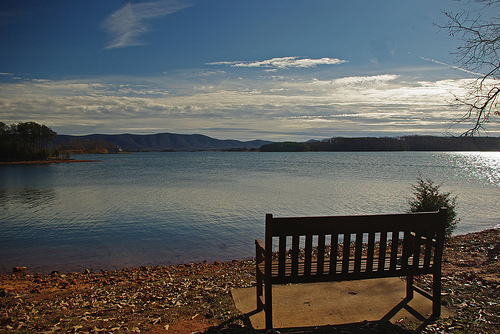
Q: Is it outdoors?
A: Yes, it is outdoors.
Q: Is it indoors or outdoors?
A: It is outdoors.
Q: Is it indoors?
A: No, it is outdoors.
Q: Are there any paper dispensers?
A: No, there are no paper dispensers.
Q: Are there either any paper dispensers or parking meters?
A: No, there are no paper dispensers or parking meters.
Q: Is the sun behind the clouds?
A: Yes, the sun is behind the clouds.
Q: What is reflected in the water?
A: The sun is reflected in the water.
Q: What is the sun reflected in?
A: The sun is reflected in the water.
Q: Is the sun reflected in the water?
A: Yes, the sun is reflected in the water.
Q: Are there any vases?
A: No, there are no vases.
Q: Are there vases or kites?
A: No, there are no vases or kites.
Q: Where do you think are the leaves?
A: The leaves are on the ground.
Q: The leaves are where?
A: The leaves are on the ground.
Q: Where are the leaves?
A: The leaves are on the ground.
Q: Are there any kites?
A: No, there are no kites.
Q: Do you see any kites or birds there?
A: No, there are no kites or birds.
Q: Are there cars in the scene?
A: No, there are no cars.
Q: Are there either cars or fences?
A: No, there are no cars or fences.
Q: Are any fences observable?
A: No, there are no fences.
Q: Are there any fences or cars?
A: No, there are no fences or cars.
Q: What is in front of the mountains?
A: The trees are in front of the mountains.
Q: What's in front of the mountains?
A: The trees are in front of the mountains.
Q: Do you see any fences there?
A: No, there are no fences.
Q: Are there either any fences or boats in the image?
A: No, there are no fences or boats.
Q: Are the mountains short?
A: Yes, the mountains are short.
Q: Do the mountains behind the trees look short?
A: Yes, the mountains are short.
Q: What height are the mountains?
A: The mountains are short.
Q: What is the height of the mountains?
A: The mountains are short.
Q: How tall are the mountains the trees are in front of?
A: The mountains are short.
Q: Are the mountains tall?
A: No, the mountains are short.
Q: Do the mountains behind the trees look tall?
A: No, the mountains are short.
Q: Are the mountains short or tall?
A: The mountains are short.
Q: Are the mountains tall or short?
A: The mountains are short.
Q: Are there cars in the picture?
A: No, there are no cars.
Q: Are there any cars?
A: No, there are no cars.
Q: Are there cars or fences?
A: No, there are no cars or fences.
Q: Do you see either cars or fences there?
A: No, there are no cars or fences.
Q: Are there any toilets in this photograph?
A: No, there are no toilets.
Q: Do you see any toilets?
A: No, there are no toilets.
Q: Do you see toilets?
A: No, there are no toilets.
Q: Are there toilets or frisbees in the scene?
A: No, there are no toilets or frisbees.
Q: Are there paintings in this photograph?
A: No, there are no paintings.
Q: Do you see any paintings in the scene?
A: No, there are no paintings.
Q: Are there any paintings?
A: No, there are no paintings.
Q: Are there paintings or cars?
A: No, there are no paintings or cars.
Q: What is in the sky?
A: The clouds are in the sky.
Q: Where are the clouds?
A: The clouds are in the sky.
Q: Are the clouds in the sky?
A: Yes, the clouds are in the sky.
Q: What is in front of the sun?
A: The clouds are in front of the sun.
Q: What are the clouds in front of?
A: The clouds are in front of the sun.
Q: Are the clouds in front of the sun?
A: Yes, the clouds are in front of the sun.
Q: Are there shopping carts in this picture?
A: No, there are no shopping carts.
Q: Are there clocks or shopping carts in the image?
A: No, there are no shopping carts or clocks.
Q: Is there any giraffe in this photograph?
A: No, there are no giraffes.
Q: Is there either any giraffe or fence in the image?
A: No, there are no giraffes or fences.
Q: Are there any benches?
A: Yes, there is a bench.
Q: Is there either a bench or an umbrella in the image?
A: Yes, there is a bench.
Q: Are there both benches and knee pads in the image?
A: No, there is a bench but no knee pads.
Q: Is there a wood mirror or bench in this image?
A: Yes, there is a wood bench.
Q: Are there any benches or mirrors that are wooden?
A: Yes, the bench is wooden.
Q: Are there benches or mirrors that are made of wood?
A: Yes, the bench is made of wood.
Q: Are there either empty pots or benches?
A: Yes, there is an empty bench.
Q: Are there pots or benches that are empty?
A: Yes, the bench is empty.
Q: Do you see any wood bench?
A: Yes, there is a wood bench.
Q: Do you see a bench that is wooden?
A: Yes, there is a bench that is wooden.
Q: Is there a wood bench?
A: Yes, there is a bench that is made of wood.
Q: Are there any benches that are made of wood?
A: Yes, there is a bench that is made of wood.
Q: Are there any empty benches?
A: Yes, there is an empty bench.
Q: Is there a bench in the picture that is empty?
A: Yes, there is a bench that is empty.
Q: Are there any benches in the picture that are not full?
A: Yes, there is a empty bench.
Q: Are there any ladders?
A: No, there are no ladders.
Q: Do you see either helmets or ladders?
A: No, there are no ladders or helmets.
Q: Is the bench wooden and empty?
A: Yes, the bench is wooden and empty.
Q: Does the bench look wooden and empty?
A: Yes, the bench is wooden and empty.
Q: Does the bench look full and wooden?
A: No, the bench is wooden but empty.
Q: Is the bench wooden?
A: Yes, the bench is wooden.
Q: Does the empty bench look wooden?
A: Yes, the bench is wooden.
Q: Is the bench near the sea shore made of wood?
A: Yes, the bench is made of wood.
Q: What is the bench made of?
A: The bench is made of wood.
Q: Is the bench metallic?
A: No, the bench is wooden.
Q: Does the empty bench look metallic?
A: No, the bench is wooden.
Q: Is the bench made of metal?
A: No, the bench is made of wood.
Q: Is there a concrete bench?
A: No, there is a bench but it is made of wood.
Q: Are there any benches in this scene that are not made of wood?
A: No, there is a bench but it is made of wood.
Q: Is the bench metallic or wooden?
A: The bench is wooden.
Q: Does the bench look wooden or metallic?
A: The bench is wooden.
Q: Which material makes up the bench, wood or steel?
A: The bench is made of wood.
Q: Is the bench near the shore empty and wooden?
A: Yes, the bench is empty and wooden.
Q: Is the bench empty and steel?
A: No, the bench is empty but wooden.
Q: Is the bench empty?
A: Yes, the bench is empty.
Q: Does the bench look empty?
A: Yes, the bench is empty.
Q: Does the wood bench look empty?
A: Yes, the bench is empty.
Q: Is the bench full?
A: No, the bench is empty.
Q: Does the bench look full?
A: No, the bench is empty.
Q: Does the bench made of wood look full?
A: No, the bench is empty.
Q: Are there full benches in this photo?
A: No, there is a bench but it is empty.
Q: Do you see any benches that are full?
A: No, there is a bench but it is empty.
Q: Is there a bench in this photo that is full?
A: No, there is a bench but it is empty.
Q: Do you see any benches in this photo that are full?
A: No, there is a bench but it is empty.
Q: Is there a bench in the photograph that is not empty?
A: No, there is a bench but it is empty.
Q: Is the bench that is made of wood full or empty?
A: The bench is empty.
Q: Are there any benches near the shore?
A: Yes, there is a bench near the shore.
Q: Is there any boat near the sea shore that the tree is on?
A: No, there is a bench near the shore.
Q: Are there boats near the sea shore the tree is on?
A: No, there is a bench near the shore.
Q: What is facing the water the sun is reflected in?
A: The bench is facing the water.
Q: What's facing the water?
A: The bench is facing the water.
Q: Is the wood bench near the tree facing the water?
A: Yes, the bench is facing the water.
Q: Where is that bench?
A: The bench is on the shore.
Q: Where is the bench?
A: The bench is on the shore.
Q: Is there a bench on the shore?
A: Yes, there is a bench on the shore.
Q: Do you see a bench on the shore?
A: Yes, there is a bench on the shore.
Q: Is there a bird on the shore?
A: No, there is a bench on the shore.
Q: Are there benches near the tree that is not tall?
A: Yes, there is a bench near the tree.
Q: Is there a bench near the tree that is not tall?
A: Yes, there is a bench near the tree.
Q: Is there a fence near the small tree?
A: No, there is a bench near the tree.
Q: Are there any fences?
A: No, there are no fences.